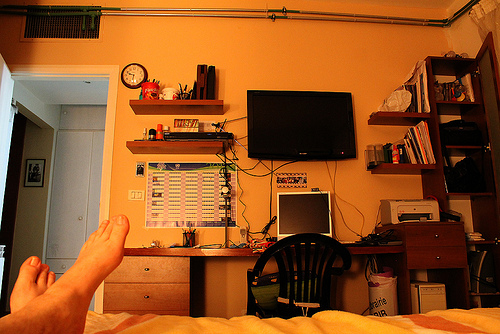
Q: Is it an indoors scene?
A: Yes, it is indoors.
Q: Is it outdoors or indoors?
A: It is indoors.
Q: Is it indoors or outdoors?
A: It is indoors.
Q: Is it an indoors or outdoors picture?
A: It is indoors.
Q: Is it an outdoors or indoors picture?
A: It is indoors.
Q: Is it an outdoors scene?
A: No, it is indoors.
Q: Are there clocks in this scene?
A: Yes, there is a clock.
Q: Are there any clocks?
A: Yes, there is a clock.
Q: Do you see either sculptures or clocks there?
A: Yes, there is a clock.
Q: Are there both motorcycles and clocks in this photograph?
A: No, there is a clock but no motorcycles.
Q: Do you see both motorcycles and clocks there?
A: No, there is a clock but no motorcycles.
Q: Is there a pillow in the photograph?
A: No, there are no pillows.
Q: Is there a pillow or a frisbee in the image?
A: No, there are no pillows or frisbees.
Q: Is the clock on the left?
A: Yes, the clock is on the left of the image.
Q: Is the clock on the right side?
A: No, the clock is on the left of the image.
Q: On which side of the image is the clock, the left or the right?
A: The clock is on the left of the image.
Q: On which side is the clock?
A: The clock is on the left of the image.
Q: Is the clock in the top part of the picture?
A: Yes, the clock is in the top of the image.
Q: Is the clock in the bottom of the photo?
A: No, the clock is in the top of the image.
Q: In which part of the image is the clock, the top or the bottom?
A: The clock is in the top of the image.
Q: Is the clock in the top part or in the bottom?
A: The clock is in the top of the image.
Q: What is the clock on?
A: The clock is on the wall.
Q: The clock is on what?
A: The clock is on the wall.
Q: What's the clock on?
A: The clock is on the wall.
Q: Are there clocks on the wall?
A: Yes, there is a clock on the wall.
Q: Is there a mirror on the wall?
A: No, there is a clock on the wall.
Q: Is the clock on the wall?
A: Yes, the clock is on the wall.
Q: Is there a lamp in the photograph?
A: No, there are no lamps.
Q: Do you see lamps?
A: No, there are no lamps.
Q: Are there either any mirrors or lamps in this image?
A: No, there are no lamps or mirrors.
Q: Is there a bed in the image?
A: Yes, there is a bed.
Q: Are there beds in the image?
A: Yes, there is a bed.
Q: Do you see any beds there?
A: Yes, there is a bed.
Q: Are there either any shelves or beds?
A: Yes, there is a bed.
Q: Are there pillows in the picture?
A: No, there are no pillows.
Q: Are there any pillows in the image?
A: No, there are no pillows.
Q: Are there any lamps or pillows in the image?
A: No, there are no pillows or lamps.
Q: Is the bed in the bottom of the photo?
A: Yes, the bed is in the bottom of the image.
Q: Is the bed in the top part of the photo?
A: No, the bed is in the bottom of the image.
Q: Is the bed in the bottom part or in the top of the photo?
A: The bed is in the bottom of the image.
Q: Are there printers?
A: Yes, there is a printer.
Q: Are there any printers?
A: Yes, there is a printer.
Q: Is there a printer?
A: Yes, there is a printer.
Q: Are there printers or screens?
A: Yes, there is a printer.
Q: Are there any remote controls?
A: No, there are no remote controls.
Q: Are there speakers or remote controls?
A: No, there are no remote controls or speakers.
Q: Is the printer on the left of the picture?
A: No, the printer is on the right of the image.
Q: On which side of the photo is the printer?
A: The printer is on the right of the image.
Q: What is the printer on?
A: The printer is on the desk.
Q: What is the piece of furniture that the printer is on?
A: The piece of furniture is a desk.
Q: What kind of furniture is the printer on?
A: The printer is on the desk.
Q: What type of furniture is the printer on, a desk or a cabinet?
A: The printer is on a desk.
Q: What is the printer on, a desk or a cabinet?
A: The printer is on a desk.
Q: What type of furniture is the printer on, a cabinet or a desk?
A: The printer is on a desk.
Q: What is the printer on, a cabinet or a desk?
A: The printer is on a desk.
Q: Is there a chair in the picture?
A: Yes, there is a chair.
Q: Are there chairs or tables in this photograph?
A: Yes, there is a chair.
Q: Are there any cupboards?
A: No, there are no cupboards.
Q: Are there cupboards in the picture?
A: No, there are no cupboards.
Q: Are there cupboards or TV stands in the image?
A: No, there are no cupboards or TV stands.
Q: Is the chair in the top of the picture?
A: No, the chair is in the bottom of the image.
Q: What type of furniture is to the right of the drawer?
A: The piece of furniture is a chair.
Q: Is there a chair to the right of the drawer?
A: Yes, there is a chair to the right of the drawer.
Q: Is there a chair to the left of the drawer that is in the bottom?
A: No, the chair is to the right of the drawer.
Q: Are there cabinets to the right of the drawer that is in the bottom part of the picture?
A: No, there is a chair to the right of the drawer.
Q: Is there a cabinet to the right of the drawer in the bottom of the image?
A: No, there is a chair to the right of the drawer.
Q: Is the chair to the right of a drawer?
A: Yes, the chair is to the right of a drawer.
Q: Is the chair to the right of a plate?
A: No, the chair is to the right of a drawer.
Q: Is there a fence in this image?
A: No, there are no fences.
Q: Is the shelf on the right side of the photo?
A: Yes, the shelf is on the right of the image.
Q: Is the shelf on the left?
A: No, the shelf is on the right of the image.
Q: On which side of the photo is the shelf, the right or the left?
A: The shelf is on the right of the image.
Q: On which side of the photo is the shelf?
A: The shelf is on the right of the image.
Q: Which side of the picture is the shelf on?
A: The shelf is on the right of the image.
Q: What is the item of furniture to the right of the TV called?
A: The piece of furniture is a shelf.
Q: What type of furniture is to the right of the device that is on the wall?
A: The piece of furniture is a shelf.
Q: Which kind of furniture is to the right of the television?
A: The piece of furniture is a shelf.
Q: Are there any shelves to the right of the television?
A: Yes, there is a shelf to the right of the television.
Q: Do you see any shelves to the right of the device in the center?
A: Yes, there is a shelf to the right of the television.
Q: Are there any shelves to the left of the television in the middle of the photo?
A: No, the shelf is to the right of the television.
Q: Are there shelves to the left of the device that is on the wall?
A: No, the shelf is to the right of the television.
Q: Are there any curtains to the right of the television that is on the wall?
A: No, there is a shelf to the right of the television.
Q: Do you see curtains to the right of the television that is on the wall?
A: No, there is a shelf to the right of the television.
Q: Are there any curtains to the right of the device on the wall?
A: No, there is a shelf to the right of the television.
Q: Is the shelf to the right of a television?
A: Yes, the shelf is to the right of a television.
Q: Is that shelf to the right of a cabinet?
A: No, the shelf is to the right of a television.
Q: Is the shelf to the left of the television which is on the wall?
A: No, the shelf is to the right of the TV.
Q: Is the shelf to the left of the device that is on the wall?
A: No, the shelf is to the right of the TV.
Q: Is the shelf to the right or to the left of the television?
A: The shelf is to the right of the television.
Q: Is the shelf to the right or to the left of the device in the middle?
A: The shelf is to the right of the television.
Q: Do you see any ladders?
A: No, there are no ladders.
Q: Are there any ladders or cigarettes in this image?
A: No, there are no ladders or cigarettes.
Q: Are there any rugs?
A: No, there are no rugs.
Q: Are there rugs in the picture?
A: No, there are no rugs.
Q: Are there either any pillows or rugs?
A: No, there are no rugs or pillows.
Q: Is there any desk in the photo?
A: Yes, there is a desk.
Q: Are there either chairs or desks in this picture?
A: Yes, there is a desk.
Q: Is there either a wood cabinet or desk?
A: Yes, there is a wood desk.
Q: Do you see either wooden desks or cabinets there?
A: Yes, there is a wood desk.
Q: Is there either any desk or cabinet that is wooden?
A: Yes, the desk is wooden.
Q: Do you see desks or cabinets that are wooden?
A: Yes, the desk is wooden.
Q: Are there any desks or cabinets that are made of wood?
A: Yes, the desk is made of wood.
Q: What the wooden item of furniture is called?
A: The piece of furniture is a desk.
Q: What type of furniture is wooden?
A: The furniture is a desk.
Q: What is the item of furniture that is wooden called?
A: The piece of furniture is a desk.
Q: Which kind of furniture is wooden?
A: The furniture is a desk.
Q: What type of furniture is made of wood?
A: The furniture is a desk.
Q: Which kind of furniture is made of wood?
A: The furniture is a desk.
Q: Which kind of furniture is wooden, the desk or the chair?
A: The desk is wooden.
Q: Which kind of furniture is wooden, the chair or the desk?
A: The desk is wooden.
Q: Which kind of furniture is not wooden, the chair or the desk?
A: The chair is not wooden.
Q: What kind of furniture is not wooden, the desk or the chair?
A: The chair is not wooden.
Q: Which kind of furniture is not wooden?
A: The furniture is a chair.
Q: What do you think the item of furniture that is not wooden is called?
A: The piece of furniture is a chair.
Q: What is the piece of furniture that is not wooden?
A: The piece of furniture is a chair.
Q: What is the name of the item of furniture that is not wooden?
A: The piece of furniture is a chair.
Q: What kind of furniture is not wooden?
A: The furniture is a chair.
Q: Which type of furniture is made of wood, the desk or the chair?
A: The desk is made of wood.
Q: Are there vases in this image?
A: No, there are no vases.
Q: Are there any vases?
A: No, there are no vases.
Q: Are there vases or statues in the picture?
A: No, there are no vases or statues.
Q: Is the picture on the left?
A: Yes, the picture is on the left of the image.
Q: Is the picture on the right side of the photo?
A: No, the picture is on the left of the image.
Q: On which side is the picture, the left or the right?
A: The picture is on the left of the image.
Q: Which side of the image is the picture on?
A: The picture is on the left of the image.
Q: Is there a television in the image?
A: Yes, there is a television.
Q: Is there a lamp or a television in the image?
A: Yes, there is a television.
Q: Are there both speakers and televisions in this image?
A: No, there is a television but no speakers.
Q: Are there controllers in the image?
A: No, there are no controllers.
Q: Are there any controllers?
A: No, there are no controllers.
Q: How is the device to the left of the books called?
A: The device is a television.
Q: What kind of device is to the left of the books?
A: The device is a television.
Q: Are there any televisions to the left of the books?
A: Yes, there is a television to the left of the books.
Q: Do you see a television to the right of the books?
A: No, the television is to the left of the books.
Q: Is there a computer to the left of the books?
A: No, there is a television to the left of the books.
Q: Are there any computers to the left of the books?
A: No, there is a television to the left of the books.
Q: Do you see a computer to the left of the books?
A: No, there is a television to the left of the books.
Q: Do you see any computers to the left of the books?
A: No, there is a television to the left of the books.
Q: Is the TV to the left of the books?
A: Yes, the TV is to the left of the books.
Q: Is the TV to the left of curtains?
A: No, the TV is to the left of the books.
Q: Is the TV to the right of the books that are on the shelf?
A: No, the TV is to the left of the books.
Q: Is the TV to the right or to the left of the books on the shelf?
A: The TV is to the left of the books.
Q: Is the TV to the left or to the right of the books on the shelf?
A: The TV is to the left of the books.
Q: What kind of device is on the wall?
A: The device is a television.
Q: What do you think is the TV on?
A: The TV is on the wall.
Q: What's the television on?
A: The TV is on the wall.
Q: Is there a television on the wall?
A: Yes, there is a television on the wall.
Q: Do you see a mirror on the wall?
A: No, there is a television on the wall.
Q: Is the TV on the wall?
A: Yes, the TV is on the wall.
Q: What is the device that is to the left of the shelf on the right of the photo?
A: The device is a television.